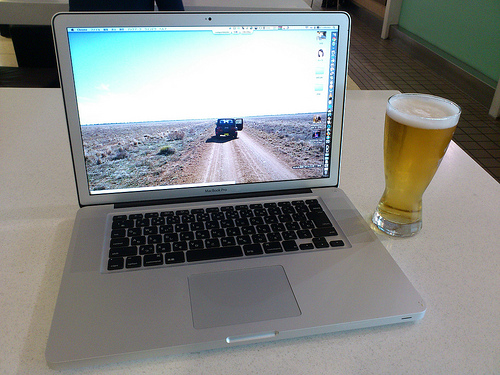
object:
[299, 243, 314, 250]
button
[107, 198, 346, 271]
keyboard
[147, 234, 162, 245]
button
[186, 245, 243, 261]
button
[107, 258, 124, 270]
button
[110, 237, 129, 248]
button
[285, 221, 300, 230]
button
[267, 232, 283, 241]
button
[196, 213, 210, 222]
button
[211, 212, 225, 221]
button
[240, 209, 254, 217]
button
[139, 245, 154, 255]
button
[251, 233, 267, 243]
button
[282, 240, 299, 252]
button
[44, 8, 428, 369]
keyboard